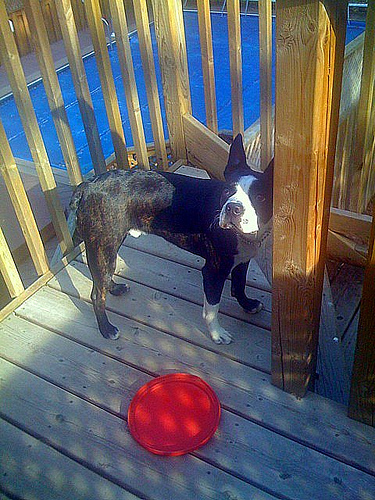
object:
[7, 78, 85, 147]
water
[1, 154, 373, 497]
ground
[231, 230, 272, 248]
collar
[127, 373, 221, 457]
bucket top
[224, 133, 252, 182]
ear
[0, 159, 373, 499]
deck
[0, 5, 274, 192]
swimming pool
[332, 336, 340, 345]
bolt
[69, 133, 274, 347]
bulldog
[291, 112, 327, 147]
ground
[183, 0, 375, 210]
railing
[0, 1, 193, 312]
railing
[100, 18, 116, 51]
ladder